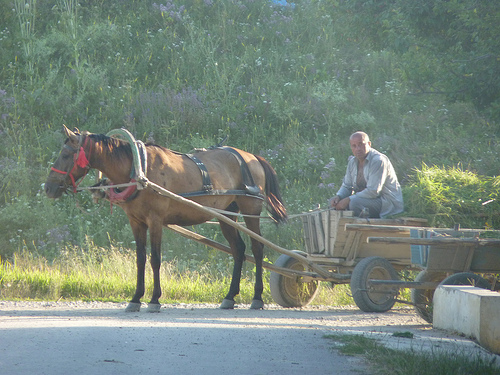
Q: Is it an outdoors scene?
A: Yes, it is outdoors.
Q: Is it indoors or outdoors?
A: It is outdoors.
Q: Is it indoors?
A: No, it is outdoors.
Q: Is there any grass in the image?
A: Yes, there is grass.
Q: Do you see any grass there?
A: Yes, there is grass.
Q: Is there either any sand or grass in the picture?
A: Yes, there is grass.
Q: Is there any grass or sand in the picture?
A: Yes, there is grass.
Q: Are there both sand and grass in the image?
A: No, there is grass but no sand.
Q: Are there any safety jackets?
A: No, there are no safety jackets.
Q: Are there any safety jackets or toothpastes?
A: No, there are no safety jackets or toothpastes.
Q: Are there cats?
A: No, there are no cats.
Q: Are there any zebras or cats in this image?
A: No, there are no cats or zebras.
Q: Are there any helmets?
A: No, there are no helmets.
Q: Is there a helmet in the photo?
A: No, there are no helmets.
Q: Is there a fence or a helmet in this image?
A: No, there are no helmets or fences.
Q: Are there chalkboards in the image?
A: No, there are no chalkboards.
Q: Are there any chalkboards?
A: No, there are no chalkboards.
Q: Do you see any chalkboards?
A: No, there are no chalkboards.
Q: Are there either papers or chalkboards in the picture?
A: No, there are no chalkboards or papers.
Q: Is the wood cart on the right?
A: Yes, the cart is on the right of the image.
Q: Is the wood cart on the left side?
A: No, the cart is on the right of the image.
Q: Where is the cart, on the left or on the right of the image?
A: The cart is on the right of the image.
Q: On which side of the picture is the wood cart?
A: The cart is on the right of the image.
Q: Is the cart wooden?
A: Yes, the cart is wooden.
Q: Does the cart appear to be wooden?
A: Yes, the cart is wooden.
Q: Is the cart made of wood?
A: Yes, the cart is made of wood.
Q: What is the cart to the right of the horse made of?
A: The cart is made of wood.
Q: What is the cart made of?
A: The cart is made of wood.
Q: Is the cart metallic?
A: No, the cart is wooden.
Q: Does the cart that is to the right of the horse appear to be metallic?
A: No, the cart is wooden.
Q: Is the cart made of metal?
A: No, the cart is made of wood.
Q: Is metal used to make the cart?
A: No, the cart is made of wood.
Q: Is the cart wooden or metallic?
A: The cart is wooden.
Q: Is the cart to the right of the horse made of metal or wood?
A: The cart is made of wood.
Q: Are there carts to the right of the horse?
A: Yes, there is a cart to the right of the horse.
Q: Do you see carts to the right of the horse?
A: Yes, there is a cart to the right of the horse.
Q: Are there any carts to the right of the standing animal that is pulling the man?
A: Yes, there is a cart to the right of the horse.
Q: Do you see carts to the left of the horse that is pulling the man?
A: No, the cart is to the right of the horse.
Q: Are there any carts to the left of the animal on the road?
A: No, the cart is to the right of the horse.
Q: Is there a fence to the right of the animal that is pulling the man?
A: No, there is a cart to the right of the horse.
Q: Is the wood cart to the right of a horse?
A: Yes, the cart is to the right of a horse.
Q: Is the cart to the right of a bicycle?
A: No, the cart is to the right of a horse.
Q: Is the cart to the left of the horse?
A: No, the cart is to the right of the horse.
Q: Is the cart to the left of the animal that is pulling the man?
A: No, the cart is to the right of the horse.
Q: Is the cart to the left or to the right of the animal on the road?
A: The cart is to the right of the horse.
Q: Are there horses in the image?
A: Yes, there is a horse.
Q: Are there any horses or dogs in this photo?
A: Yes, there is a horse.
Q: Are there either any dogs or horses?
A: Yes, there is a horse.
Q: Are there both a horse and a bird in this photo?
A: No, there is a horse but no birds.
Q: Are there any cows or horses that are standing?
A: Yes, the horse is standing.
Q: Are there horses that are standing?
A: Yes, there is a horse that is standing.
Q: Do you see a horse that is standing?
A: Yes, there is a horse that is standing.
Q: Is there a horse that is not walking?
A: Yes, there is a horse that is standing.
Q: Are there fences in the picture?
A: No, there are no fences.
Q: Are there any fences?
A: No, there are no fences.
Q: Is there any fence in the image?
A: No, there are no fences.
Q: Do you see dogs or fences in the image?
A: No, there are no fences or dogs.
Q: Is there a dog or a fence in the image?
A: No, there are no fences or dogs.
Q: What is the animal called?
A: The animal is a horse.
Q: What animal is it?
A: The animal is a horse.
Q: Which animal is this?
A: This is a horse.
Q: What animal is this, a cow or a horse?
A: This is a horse.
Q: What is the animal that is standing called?
A: The animal is a horse.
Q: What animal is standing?
A: The animal is a horse.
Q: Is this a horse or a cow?
A: This is a horse.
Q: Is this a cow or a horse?
A: This is a horse.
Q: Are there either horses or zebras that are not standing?
A: No, there is a horse but it is standing.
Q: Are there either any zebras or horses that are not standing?
A: No, there is a horse but it is standing.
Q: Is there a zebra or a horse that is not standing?
A: No, there is a horse but it is standing.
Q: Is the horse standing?
A: Yes, the horse is standing.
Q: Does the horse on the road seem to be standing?
A: Yes, the horse is standing.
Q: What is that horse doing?
A: The horse is standing.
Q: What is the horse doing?
A: The horse is standing.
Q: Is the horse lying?
A: No, the horse is standing.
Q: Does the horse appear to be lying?
A: No, the horse is standing.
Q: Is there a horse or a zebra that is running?
A: No, there is a horse but it is standing.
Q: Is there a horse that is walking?
A: No, there is a horse but it is standing.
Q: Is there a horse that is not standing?
A: No, there is a horse but it is standing.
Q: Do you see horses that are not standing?
A: No, there is a horse but it is standing.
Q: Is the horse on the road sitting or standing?
A: The horse is standing.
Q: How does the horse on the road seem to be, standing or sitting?
A: The horse is standing.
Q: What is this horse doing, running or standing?
A: The horse is standing.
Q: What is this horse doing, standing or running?
A: The horse is standing.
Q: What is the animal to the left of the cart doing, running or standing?
A: The horse is standing.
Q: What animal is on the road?
A: The horse is on the road.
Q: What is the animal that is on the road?
A: The animal is a horse.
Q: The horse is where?
A: The horse is on the road.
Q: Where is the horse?
A: The horse is on the road.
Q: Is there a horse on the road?
A: Yes, there is a horse on the road.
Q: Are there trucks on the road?
A: No, there is a horse on the road.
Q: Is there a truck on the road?
A: No, there is a horse on the road.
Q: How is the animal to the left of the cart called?
A: The animal is a horse.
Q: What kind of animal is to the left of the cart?
A: The animal is a horse.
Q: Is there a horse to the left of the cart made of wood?
A: Yes, there is a horse to the left of the cart.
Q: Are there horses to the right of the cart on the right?
A: No, the horse is to the left of the cart.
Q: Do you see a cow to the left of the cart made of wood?
A: No, there is a horse to the left of the cart.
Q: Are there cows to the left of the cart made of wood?
A: No, there is a horse to the left of the cart.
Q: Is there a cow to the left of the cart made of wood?
A: No, there is a horse to the left of the cart.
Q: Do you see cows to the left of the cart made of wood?
A: No, there is a horse to the left of the cart.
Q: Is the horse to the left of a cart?
A: Yes, the horse is to the left of a cart.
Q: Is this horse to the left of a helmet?
A: No, the horse is to the left of a cart.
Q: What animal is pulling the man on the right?
A: The horse is pulling the man.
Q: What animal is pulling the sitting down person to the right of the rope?
A: The horse is pulling the man.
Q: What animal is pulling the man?
A: The horse is pulling the man.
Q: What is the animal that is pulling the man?
A: The animal is a horse.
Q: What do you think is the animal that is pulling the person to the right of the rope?
A: The animal is a horse.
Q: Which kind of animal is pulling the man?
A: The animal is a horse.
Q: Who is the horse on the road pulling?
A: The horse is pulling the man.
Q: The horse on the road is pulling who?
A: The horse is pulling the man.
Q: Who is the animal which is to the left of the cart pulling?
A: The horse is pulling the man.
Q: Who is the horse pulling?
A: The horse is pulling the man.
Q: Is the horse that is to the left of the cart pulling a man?
A: Yes, the horse is pulling a man.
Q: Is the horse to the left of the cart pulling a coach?
A: No, the horse is pulling a man.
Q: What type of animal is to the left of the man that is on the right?
A: The animal is a horse.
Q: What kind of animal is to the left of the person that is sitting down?
A: The animal is a horse.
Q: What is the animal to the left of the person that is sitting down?
A: The animal is a horse.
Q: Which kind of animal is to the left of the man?
A: The animal is a horse.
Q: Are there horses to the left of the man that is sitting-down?
A: Yes, there is a horse to the left of the man.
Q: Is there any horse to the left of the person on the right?
A: Yes, there is a horse to the left of the man.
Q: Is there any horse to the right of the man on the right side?
A: No, the horse is to the left of the man.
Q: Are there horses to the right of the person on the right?
A: No, the horse is to the left of the man.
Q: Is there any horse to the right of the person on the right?
A: No, the horse is to the left of the man.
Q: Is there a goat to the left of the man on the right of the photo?
A: No, there is a horse to the left of the man.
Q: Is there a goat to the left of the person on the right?
A: No, there is a horse to the left of the man.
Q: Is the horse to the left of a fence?
A: No, the horse is to the left of the man.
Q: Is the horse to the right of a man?
A: No, the horse is to the left of a man.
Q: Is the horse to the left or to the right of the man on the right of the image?
A: The horse is to the left of the man.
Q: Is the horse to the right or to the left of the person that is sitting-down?
A: The horse is to the left of the man.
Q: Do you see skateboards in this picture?
A: No, there are no skateboards.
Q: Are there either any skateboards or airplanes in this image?
A: No, there are no skateboards or airplanes.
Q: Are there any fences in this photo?
A: No, there are no fences.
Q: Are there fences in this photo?
A: No, there are no fences.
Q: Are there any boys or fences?
A: No, there are no fences or boys.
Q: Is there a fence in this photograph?
A: No, there are no fences.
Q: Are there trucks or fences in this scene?
A: No, there are no fences or trucks.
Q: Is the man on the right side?
A: Yes, the man is on the right of the image.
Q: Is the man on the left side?
A: No, the man is on the right of the image.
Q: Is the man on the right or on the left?
A: The man is on the right of the image.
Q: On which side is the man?
A: The man is on the right of the image.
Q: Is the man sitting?
A: Yes, the man is sitting.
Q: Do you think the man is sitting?
A: Yes, the man is sitting.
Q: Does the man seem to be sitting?
A: Yes, the man is sitting.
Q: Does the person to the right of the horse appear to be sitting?
A: Yes, the man is sitting.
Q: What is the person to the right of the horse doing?
A: The man is sitting.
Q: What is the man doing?
A: The man is sitting.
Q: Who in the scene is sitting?
A: The man is sitting.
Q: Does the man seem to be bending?
A: No, the man is sitting.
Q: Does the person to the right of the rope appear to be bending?
A: No, the man is sitting.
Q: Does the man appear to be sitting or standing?
A: The man is sitting.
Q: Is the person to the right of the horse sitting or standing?
A: The man is sitting.